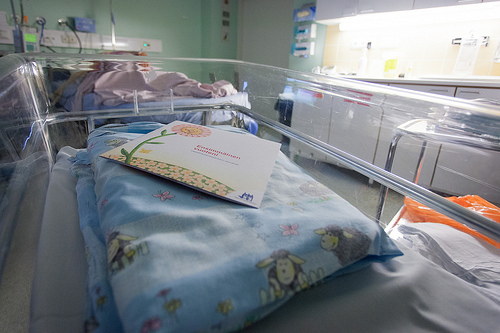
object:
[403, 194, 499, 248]
bag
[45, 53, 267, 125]
person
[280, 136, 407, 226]
ground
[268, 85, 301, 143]
trash bin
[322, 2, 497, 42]
lighting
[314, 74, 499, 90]
counter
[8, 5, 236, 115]
wall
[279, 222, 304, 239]
butterfly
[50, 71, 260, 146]
hospital bed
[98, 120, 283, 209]
card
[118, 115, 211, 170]
yellow flower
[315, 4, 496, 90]
lights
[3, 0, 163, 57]
medical supplies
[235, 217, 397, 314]
sheep design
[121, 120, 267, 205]
envelope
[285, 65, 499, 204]
white cabinets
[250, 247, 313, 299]
sheep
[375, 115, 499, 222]
tray table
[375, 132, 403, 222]
leg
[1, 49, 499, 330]
baby bed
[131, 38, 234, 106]
light bed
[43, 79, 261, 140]
bed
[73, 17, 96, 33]
equipment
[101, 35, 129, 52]
light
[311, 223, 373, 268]
black sheep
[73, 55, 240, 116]
blanket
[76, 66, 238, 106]
sheet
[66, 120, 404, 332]
blanket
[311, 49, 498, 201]
white cabinets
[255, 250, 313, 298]
animal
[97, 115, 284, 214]
pamphlet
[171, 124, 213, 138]
flower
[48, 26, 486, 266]
scene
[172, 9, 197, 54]
wall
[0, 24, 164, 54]
outlet strip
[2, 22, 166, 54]
medical equipment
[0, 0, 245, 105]
wall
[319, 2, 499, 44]
light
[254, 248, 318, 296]
sheep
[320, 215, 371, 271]
sheep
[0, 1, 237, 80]
wall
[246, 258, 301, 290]
sheep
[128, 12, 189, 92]
light